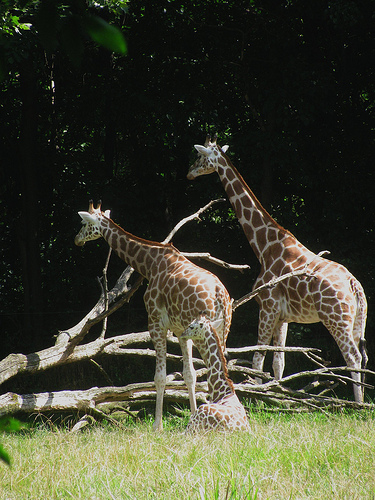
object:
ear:
[220, 145, 229, 152]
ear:
[194, 144, 207, 154]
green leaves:
[0, 0, 138, 205]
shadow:
[24, 352, 39, 372]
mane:
[102, 215, 171, 246]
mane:
[209, 323, 234, 393]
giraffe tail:
[349, 278, 365, 390]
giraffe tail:
[215, 286, 228, 345]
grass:
[0, 415, 374, 500]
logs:
[2, 381, 348, 420]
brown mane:
[219, 146, 295, 238]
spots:
[178, 277, 188, 290]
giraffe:
[188, 140, 368, 403]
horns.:
[212, 134, 217, 144]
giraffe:
[76, 200, 234, 426]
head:
[186, 135, 229, 179]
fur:
[268, 229, 277, 241]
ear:
[78, 211, 94, 221]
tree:
[260, 0, 375, 210]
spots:
[282, 236, 296, 246]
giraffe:
[181, 311, 250, 432]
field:
[1, 410, 373, 499]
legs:
[149, 315, 166, 420]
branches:
[72, 199, 216, 338]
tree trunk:
[0, 387, 100, 416]